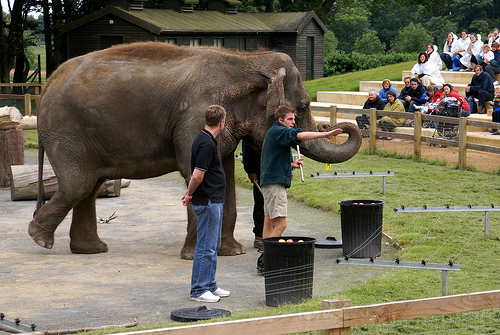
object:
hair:
[203, 104, 226, 125]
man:
[182, 104, 233, 302]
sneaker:
[213, 286, 230, 297]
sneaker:
[191, 290, 220, 301]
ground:
[1, 59, 500, 335]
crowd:
[462, 65, 496, 117]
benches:
[310, 101, 499, 124]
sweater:
[258, 120, 300, 189]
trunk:
[288, 107, 364, 162]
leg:
[27, 103, 98, 233]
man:
[256, 105, 343, 271]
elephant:
[28, 40, 361, 259]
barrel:
[339, 198, 384, 258]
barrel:
[261, 236, 316, 306]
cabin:
[56, 0, 329, 88]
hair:
[275, 105, 297, 121]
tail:
[36, 105, 48, 219]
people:
[413, 54, 450, 86]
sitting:
[378, 93, 413, 140]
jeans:
[191, 204, 227, 297]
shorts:
[255, 185, 285, 221]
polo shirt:
[186, 130, 226, 207]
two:
[174, 105, 345, 305]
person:
[432, 83, 471, 117]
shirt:
[449, 90, 472, 110]